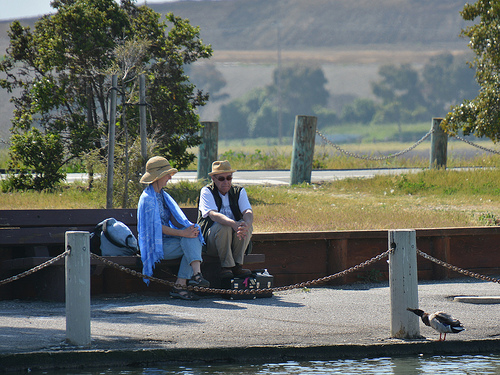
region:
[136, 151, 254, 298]
Couple sitting on a bench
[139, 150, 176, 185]
Large brown colored hat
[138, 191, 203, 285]
Blue shoal over shoulder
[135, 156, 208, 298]
Woman sitting on a bench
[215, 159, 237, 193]
Man wearing dark sunglasses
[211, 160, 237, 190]
Man wearing a hat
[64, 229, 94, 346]
Short gray wooden log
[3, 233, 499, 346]
Wood and metal fence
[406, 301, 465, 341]
Bird standing beside water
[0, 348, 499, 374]
Water beside concrete path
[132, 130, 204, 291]
woman wearing beige hat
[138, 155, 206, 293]
woman with her legs crossed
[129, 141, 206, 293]
woman wearing light blue shawl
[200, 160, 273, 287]
man wearing green vest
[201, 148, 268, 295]
man wearing sunglasses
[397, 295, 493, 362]
bird next to wood pole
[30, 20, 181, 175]
small tree behind bench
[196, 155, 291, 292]
man with his foot on case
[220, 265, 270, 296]
black case on the ground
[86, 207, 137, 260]
white backpack on bench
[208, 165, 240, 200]
the head of a man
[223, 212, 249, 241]
the hands of a man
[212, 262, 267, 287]
the feet of a man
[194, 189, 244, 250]
the arm of a man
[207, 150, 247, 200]
a man wearing sunglasses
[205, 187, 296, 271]
a man wearing pants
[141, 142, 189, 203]
the head of a woman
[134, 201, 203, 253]
the arm of a woman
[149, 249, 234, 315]
the feet of a woman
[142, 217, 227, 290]
a woman wearing pants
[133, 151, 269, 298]
TWO PEOPLE ARE SITTING ON A BENCH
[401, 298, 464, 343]
A DUCK IS STRETCHING ITS NECK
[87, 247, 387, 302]
CHAINS ARE LOOPED BETWEEN THE POLES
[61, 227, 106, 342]
POLES ARE WHITE IN COLOR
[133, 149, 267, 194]
BOTH PEOPLE ARE WEARING HATS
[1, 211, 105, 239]
WOODEN PIECES ON BENCH ARE SLATS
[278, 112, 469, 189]
POLES IN BACKGROUND ARE TAN IN COLOR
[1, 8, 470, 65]
A MOUNTAIN IS VISIBLE IN THE BACKGROUND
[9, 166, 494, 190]
A ROAD DIVIDES THE TWO GRASSY AREAS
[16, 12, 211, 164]
TREE LEAVES ARE A GREEN COLOR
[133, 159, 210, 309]
woman wearing blue sweater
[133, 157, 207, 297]
woman wearing blue shirt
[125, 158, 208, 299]
woman wearing gray pants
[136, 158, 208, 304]
woman wearing black shoes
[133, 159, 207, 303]
woman wearing tan hat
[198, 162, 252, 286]
woman wearing tan hat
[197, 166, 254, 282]
woman wearing white shirt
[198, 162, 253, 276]
woman wearing sun glasses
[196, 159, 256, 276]
woman wearing dark vest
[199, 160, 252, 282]
woman wearing brown pants